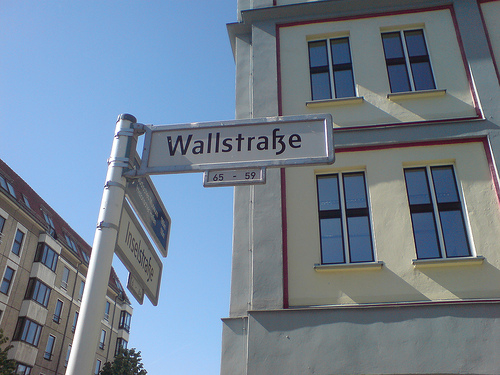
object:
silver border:
[138, 113, 336, 187]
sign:
[114, 150, 171, 305]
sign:
[139, 113, 335, 187]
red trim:
[280, 136, 499, 309]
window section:
[403, 162, 474, 260]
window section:
[308, 27, 437, 102]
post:
[64, 113, 136, 375]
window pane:
[319, 216, 345, 265]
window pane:
[346, 213, 375, 263]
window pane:
[316, 173, 342, 210]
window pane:
[342, 170, 374, 209]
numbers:
[203, 167, 267, 187]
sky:
[0, 0, 236, 375]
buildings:
[0, 158, 134, 375]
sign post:
[63, 113, 335, 375]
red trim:
[276, 0, 500, 130]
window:
[308, 36, 357, 100]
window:
[380, 28, 437, 94]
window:
[316, 171, 374, 264]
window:
[403, 164, 473, 261]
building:
[219, 0, 500, 375]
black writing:
[166, 128, 300, 156]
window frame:
[307, 36, 356, 101]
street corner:
[0, 104, 375, 375]